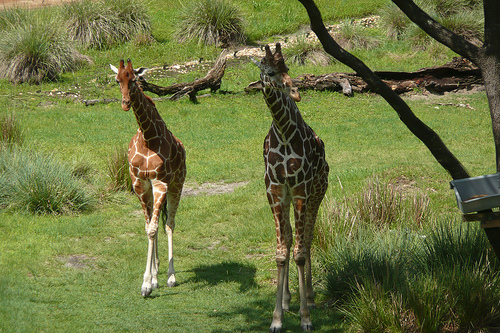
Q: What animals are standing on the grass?
A: Giraffes.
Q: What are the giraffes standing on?
A: Grass.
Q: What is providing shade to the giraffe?
A: A tree.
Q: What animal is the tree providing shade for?
A: The giraffe.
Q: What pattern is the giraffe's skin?
A: Spots.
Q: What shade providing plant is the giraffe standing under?
A: The tree.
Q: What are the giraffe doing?
A: Walking in field.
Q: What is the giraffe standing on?
A: In the grass.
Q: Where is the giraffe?
A: Under a tree.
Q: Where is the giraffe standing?
A: In the grass.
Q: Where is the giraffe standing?
A: Next to a tree.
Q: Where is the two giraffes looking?
A: Forward.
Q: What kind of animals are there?
A: Giraffes.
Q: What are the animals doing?
A: Standing.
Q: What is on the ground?
A: Shadow of animal.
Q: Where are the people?
A: None in photo.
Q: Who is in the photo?
A: No people.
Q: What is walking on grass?
A: Giraffe.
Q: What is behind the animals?
A: Grass.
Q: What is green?
A: Grass.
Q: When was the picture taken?
A: Daytime.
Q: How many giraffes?
A: Two.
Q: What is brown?
A: Giraffe.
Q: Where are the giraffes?
A: Zoo.